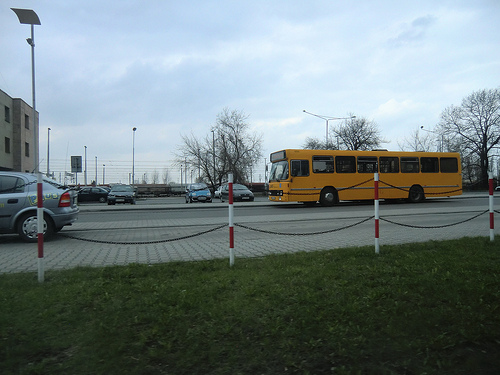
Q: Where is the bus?
A: On the road.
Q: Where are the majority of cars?
A: In the parking lot.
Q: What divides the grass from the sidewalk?
A: A roped fence.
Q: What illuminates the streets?
A: Street lamps.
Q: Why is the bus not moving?
A: It is parked.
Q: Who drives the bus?
A: A bus driver.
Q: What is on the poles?
A: Chain.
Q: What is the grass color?
A: Green.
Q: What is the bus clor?
A: Yellow.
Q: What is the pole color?
A: Red.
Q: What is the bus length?
A: Long.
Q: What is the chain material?
A: Metal.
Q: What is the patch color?
A: Green.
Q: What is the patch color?
A: Green.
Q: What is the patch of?
A: Grass.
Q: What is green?
A: Grass.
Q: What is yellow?
A: Bus.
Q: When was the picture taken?
A: Daytime.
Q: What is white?
A: Clouds.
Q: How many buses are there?
A: One.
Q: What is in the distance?
A: Trees.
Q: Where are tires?
A: On a bus.